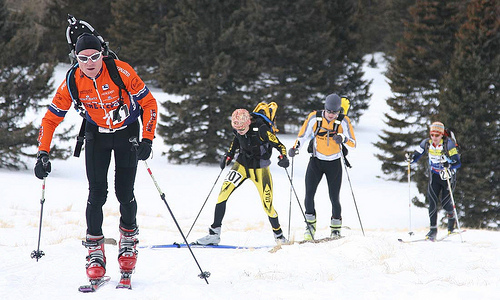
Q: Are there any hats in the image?
A: Yes, there is a hat.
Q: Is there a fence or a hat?
A: Yes, there is a hat.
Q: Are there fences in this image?
A: No, there are no fences.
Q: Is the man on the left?
A: Yes, the man is on the left of the image.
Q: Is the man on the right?
A: No, the man is on the left of the image.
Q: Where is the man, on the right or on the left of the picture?
A: The man is on the left of the image.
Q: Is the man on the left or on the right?
A: The man is on the left of the image.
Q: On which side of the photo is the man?
A: The man is on the left of the image.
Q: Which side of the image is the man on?
A: The man is on the left of the image.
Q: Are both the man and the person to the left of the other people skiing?
A: Yes, both the man and the person are skiing.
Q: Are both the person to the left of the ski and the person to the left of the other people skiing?
A: Yes, both the man and the person are skiing.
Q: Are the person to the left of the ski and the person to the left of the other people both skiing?
A: Yes, both the man and the person are skiing.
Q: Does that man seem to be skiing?
A: Yes, the man is skiing.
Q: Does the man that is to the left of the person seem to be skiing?
A: Yes, the man is skiing.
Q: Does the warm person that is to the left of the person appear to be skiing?
A: Yes, the man is skiing.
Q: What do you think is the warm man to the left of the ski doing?
A: The man is skiing.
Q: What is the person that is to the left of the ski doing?
A: The man is skiing.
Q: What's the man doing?
A: The man is skiing.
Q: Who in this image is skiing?
A: The man is skiing.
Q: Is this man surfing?
A: No, the man is skiing.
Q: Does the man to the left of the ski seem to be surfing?
A: No, the man is skiing.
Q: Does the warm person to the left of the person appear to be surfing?
A: No, the man is skiing.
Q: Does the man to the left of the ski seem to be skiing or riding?
A: The man is skiing.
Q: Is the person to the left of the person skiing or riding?
A: The man is skiing.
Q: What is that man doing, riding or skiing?
A: The man is skiing.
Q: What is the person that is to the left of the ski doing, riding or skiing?
A: The man is skiing.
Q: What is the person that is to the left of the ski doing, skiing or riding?
A: The man is skiing.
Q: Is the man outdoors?
A: Yes, the man is outdoors.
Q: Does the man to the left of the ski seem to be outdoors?
A: Yes, the man is outdoors.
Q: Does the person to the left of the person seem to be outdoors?
A: Yes, the man is outdoors.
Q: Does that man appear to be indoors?
A: No, the man is outdoors.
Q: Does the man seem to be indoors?
A: No, the man is outdoors.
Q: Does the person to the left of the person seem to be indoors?
A: No, the man is outdoors.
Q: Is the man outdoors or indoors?
A: The man is outdoors.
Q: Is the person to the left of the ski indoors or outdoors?
A: The man is outdoors.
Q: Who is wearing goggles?
A: The man is wearing goggles.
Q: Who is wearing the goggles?
A: The man is wearing goggles.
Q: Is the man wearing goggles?
A: Yes, the man is wearing goggles.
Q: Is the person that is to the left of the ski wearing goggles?
A: Yes, the man is wearing goggles.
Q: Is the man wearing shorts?
A: No, the man is wearing goggles.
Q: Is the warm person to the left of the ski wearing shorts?
A: No, the man is wearing goggles.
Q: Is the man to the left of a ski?
A: Yes, the man is to the left of a ski.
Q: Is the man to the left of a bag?
A: No, the man is to the left of a ski.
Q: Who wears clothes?
A: The man wears clothes.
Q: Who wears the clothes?
A: The man wears clothes.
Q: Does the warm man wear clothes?
A: Yes, the man wears clothes.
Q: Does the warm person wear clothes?
A: Yes, the man wears clothes.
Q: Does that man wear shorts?
A: No, the man wears clothes.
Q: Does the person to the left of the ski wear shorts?
A: No, the man wears clothes.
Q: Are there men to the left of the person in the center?
A: Yes, there is a man to the left of the person.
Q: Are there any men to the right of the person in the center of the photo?
A: No, the man is to the left of the person.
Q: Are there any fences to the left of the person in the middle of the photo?
A: No, there is a man to the left of the person.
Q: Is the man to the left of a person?
A: Yes, the man is to the left of a person.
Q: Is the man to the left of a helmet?
A: No, the man is to the left of a person.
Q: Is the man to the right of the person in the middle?
A: No, the man is to the left of the person.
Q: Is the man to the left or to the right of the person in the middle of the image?
A: The man is to the left of the person.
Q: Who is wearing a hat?
A: The man is wearing a hat.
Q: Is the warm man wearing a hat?
A: Yes, the man is wearing a hat.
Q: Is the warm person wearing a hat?
A: Yes, the man is wearing a hat.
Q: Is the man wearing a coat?
A: No, the man is wearing a hat.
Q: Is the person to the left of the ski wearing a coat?
A: No, the man is wearing a hat.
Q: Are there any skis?
A: Yes, there are skis.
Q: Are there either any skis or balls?
A: Yes, there are skis.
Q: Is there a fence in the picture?
A: No, there are no fences.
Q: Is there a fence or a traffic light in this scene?
A: No, there are no fences or traffic lights.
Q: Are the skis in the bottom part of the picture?
A: Yes, the skis are in the bottom of the image.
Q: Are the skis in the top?
A: No, the skis are in the bottom of the image.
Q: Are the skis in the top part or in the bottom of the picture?
A: The skis are in the bottom of the image.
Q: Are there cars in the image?
A: No, there are no cars.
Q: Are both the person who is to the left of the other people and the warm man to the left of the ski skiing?
A: Yes, both the person and the man are skiing.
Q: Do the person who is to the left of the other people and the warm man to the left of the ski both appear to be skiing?
A: Yes, both the person and the man are skiing.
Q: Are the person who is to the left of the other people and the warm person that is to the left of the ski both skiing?
A: Yes, both the person and the man are skiing.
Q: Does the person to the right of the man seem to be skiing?
A: Yes, the person is skiing.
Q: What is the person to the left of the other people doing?
A: The person is skiing.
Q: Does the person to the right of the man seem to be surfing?
A: No, the person is skiing.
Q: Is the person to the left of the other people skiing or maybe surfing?
A: The person is skiing.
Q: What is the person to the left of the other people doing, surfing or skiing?
A: The person is skiing.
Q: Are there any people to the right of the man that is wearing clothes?
A: Yes, there is a person to the right of the man.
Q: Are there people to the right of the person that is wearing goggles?
A: Yes, there is a person to the right of the man.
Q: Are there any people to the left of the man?
A: No, the person is to the right of the man.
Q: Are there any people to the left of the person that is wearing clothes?
A: No, the person is to the right of the man.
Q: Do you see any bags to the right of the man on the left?
A: No, there is a person to the right of the man.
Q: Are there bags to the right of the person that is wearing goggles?
A: No, there is a person to the right of the man.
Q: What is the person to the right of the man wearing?
A: The person is wearing a hat.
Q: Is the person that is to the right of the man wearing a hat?
A: Yes, the person is wearing a hat.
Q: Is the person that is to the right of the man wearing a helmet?
A: No, the person is wearing a hat.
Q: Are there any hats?
A: Yes, there is a hat.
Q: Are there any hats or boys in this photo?
A: Yes, there is a hat.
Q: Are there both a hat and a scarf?
A: No, there is a hat but no scarves.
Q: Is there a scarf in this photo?
A: No, there are no scarves.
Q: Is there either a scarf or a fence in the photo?
A: No, there are no scarves or fences.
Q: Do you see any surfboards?
A: No, there are no surfboards.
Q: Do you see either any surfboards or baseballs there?
A: No, there are no surfboards or baseballs.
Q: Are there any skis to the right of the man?
A: Yes, there is a ski to the right of the man.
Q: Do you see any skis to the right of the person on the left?
A: Yes, there is a ski to the right of the man.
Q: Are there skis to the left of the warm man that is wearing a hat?
A: No, the ski is to the right of the man.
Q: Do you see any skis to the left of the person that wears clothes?
A: No, the ski is to the right of the man.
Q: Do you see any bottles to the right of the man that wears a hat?
A: No, there is a ski to the right of the man.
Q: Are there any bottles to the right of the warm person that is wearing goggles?
A: No, there is a ski to the right of the man.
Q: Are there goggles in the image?
A: Yes, there are goggles.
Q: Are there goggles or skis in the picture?
A: Yes, there are goggles.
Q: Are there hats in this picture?
A: Yes, there is a hat.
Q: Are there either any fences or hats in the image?
A: Yes, there is a hat.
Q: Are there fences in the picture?
A: No, there are no fences.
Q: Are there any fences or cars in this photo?
A: No, there are no fences or cars.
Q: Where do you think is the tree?
A: The tree is on the snow.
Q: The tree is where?
A: The tree is on the snow.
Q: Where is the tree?
A: The tree is on the snow.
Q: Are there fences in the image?
A: No, there are no fences.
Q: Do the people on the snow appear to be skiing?
A: Yes, the people are skiing.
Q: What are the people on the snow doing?
A: The people are skiing.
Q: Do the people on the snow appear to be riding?
A: No, the people are skiing.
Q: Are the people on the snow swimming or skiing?
A: The people are skiing.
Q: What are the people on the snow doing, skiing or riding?
A: The people are skiing.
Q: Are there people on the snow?
A: Yes, there are people on the snow.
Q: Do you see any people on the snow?
A: Yes, there are people on the snow.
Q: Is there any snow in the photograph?
A: Yes, there is snow.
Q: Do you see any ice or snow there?
A: Yes, there is snow.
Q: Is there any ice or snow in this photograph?
A: Yes, there is snow.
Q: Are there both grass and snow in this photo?
A: No, there is snow but no grass.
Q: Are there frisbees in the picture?
A: No, there are no frisbees.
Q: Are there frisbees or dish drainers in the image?
A: No, there are no frisbees or dish drainers.